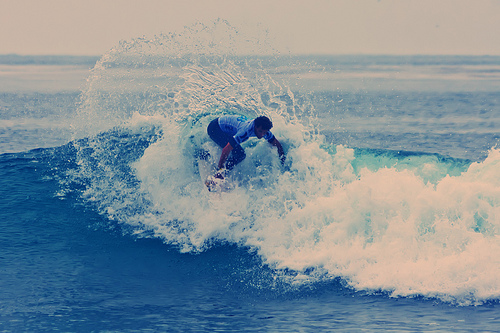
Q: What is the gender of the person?
A: Male.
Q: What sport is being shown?
A: Surfing.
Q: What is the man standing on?
A: Surfboard.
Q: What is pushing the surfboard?
A: Wave.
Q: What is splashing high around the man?
A: Water.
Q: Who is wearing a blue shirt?
A: The surfer.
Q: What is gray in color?
A: Sky.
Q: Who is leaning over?
A: The surfer.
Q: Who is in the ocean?
A: The man.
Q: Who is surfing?
A: The man.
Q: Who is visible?
A: The man.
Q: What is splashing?
A: The water.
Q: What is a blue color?
A: Ocean.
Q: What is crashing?
A: The wave.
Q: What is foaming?
A: The wave.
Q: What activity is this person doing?
A: Surfing.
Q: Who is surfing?
A: A man.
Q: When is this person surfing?
A: Day time.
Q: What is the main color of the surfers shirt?
A: White.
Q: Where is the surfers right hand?
A: Down by his right foot.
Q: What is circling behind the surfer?
A: Wave.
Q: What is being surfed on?
A: Water.